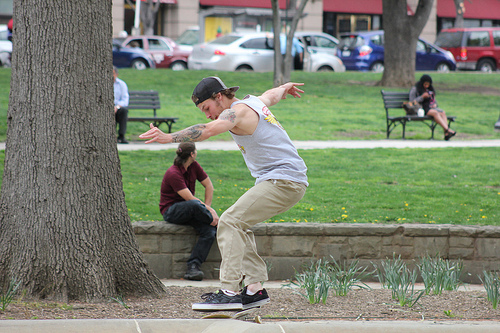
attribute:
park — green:
[113, 70, 496, 221]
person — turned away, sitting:
[158, 140, 220, 281]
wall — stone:
[133, 224, 497, 285]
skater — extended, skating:
[137, 74, 309, 313]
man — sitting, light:
[112, 65, 130, 145]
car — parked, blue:
[335, 29, 458, 74]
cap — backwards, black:
[190, 76, 239, 108]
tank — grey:
[226, 90, 311, 187]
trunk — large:
[0, 10, 168, 304]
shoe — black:
[190, 289, 245, 311]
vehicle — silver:
[189, 29, 349, 73]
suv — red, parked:
[433, 26, 499, 71]